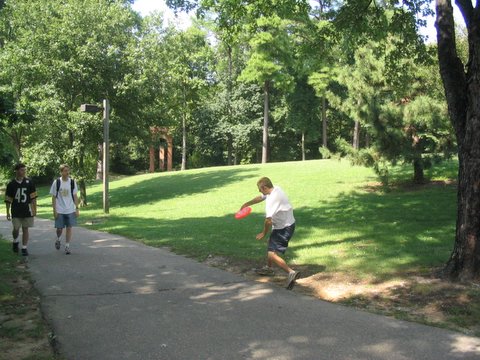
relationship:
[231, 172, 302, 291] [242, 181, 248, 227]
man getting ready to throw frisbee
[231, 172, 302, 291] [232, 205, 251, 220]
man holding a disc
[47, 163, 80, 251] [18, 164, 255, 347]
man walking on sidewalk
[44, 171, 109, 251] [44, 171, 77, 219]
man wearing backpack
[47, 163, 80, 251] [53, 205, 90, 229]
man wearing shorts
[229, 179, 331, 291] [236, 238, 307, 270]
man wearing shorts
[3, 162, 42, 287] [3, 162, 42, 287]
man wearing jersey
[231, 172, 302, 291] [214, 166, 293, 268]
man holding frisbee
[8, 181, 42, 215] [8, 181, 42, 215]
number on jersey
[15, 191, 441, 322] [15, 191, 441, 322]
shadow on walkway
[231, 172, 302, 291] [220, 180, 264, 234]
man throwing disc